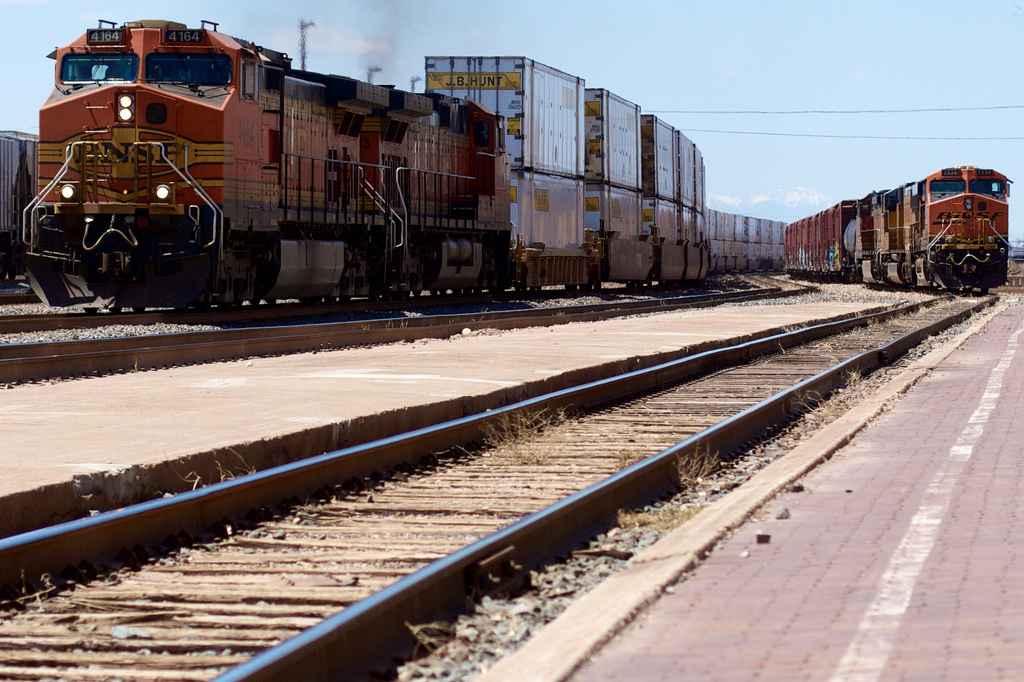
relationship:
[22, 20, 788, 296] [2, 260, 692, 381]
cars on tracks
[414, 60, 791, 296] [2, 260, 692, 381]
cars on tracks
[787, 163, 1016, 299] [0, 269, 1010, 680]
long train on tracks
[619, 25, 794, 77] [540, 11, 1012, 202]
clouds in blue sky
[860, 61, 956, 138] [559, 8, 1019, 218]
white clouds in blue sky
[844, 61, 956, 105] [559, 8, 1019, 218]
white clouds in blue sky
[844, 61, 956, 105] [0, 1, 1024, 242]
white clouds in blue sky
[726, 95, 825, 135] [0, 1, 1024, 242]
white skys in blue sky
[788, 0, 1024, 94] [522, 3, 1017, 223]
white skys in blue sky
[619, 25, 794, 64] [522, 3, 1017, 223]
clouds in blue sky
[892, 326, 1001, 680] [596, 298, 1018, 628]
dash on pathway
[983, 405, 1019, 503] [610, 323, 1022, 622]
bricks on road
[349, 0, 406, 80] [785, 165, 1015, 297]
smoke out of long train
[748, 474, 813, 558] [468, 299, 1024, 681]
stones on pathway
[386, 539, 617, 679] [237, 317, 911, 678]
stones beside railing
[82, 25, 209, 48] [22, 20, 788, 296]
numbers in front of cars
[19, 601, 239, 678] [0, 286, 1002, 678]
wood on track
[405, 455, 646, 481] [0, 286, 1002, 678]
wood on track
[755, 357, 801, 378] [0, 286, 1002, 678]
wood on track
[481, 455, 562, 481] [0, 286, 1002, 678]
wood on track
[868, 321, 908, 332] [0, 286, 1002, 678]
wood on track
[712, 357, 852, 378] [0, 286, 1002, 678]
wood on track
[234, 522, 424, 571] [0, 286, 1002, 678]
wood on track